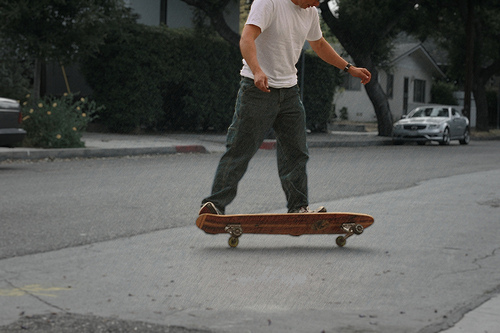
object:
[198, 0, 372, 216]
man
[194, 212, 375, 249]
skateboard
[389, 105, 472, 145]
car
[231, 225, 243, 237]
wheels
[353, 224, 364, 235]
wheels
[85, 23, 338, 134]
hedges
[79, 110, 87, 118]
flower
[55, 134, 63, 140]
flower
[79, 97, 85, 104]
flower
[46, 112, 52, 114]
flower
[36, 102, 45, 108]
flower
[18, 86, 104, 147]
plant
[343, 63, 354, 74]
watch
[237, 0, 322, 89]
shirt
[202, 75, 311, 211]
jeans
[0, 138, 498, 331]
street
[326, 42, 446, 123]
house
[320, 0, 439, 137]
tree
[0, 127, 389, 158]
sidewalk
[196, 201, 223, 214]
shoes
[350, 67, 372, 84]
hand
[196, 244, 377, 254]
shadow